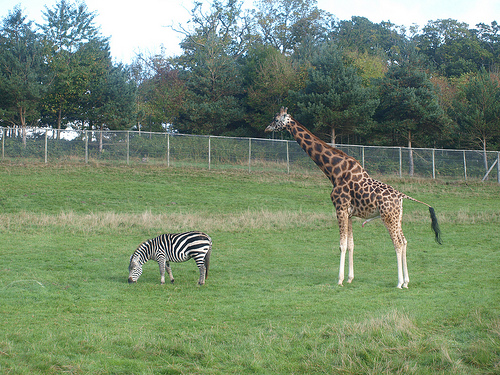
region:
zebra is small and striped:
[117, 215, 238, 295]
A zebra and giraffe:
[79, 163, 256, 320]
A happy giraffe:
[356, 215, 381, 236]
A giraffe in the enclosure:
[101, 72, 468, 222]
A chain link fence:
[102, 115, 237, 172]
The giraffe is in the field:
[264, 83, 489, 318]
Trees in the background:
[46, 41, 266, 111]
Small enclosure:
[57, 103, 496, 334]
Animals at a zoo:
[93, 69, 482, 334]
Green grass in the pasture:
[124, 291, 330, 361]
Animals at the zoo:
[69, 96, 486, 329]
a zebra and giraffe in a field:
[80, 90, 458, 320]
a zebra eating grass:
[92, 222, 236, 288]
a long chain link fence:
[136, 145, 493, 170]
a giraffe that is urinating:
[250, 90, 434, 300]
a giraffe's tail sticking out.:
[382, 182, 458, 255]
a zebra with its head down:
[81, 222, 243, 301]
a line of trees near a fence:
[2, 23, 476, 159]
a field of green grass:
[2, 170, 304, 370]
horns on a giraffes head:
[259, 97, 295, 139]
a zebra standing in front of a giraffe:
[83, 69, 452, 293]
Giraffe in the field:
[261, 58, 435, 314]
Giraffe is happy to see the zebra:
[296, 13, 449, 305]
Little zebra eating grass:
[109, 207, 240, 300]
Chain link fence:
[141, 119, 243, 184]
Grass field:
[242, 180, 339, 332]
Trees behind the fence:
[152, 47, 280, 107]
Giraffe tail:
[411, 188, 471, 280]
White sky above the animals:
[98, 1, 196, 71]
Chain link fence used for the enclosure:
[97, 117, 307, 184]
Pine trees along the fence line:
[298, 40, 468, 147]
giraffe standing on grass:
[265, 102, 452, 293]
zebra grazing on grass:
[120, 226, 222, 291]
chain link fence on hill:
[170, 131, 257, 173]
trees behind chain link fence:
[130, 54, 257, 131]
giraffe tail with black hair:
[400, 190, 452, 244]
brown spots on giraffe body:
[328, 156, 378, 206]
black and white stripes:
[166, 237, 195, 255]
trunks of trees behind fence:
[17, 117, 67, 148]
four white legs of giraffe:
[320, 250, 430, 292]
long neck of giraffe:
[292, 125, 342, 172]